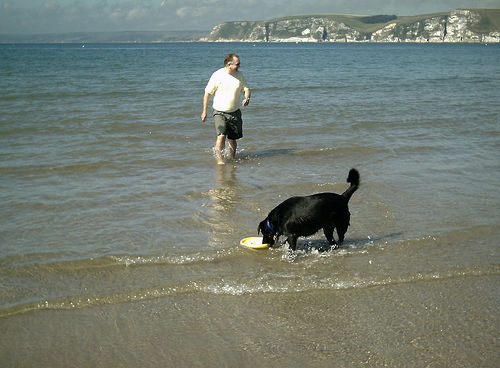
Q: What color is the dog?
A: Black.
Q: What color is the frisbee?
A: Yellow.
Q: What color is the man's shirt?
A: White.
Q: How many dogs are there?
A: One.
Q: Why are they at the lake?
A: To play.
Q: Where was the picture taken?
A: The lake.